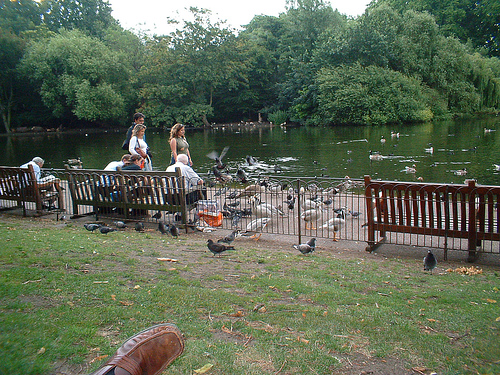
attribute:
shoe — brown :
[96, 319, 181, 373]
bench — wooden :
[360, 174, 498, 259]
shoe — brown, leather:
[115, 311, 193, 372]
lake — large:
[8, 122, 498, 188]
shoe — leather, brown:
[56, 321, 256, 368]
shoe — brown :
[92, 315, 192, 374]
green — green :
[9, 232, 494, 374]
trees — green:
[15, 5, 473, 132]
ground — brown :
[4, 218, 498, 375]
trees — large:
[5, 49, 498, 147]